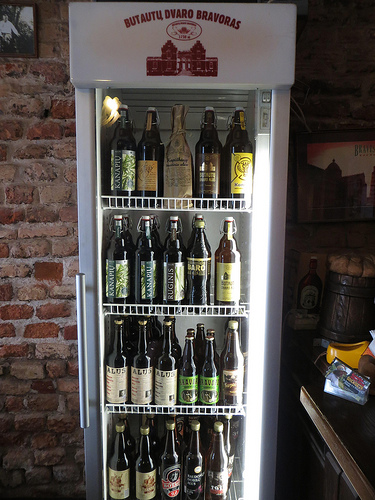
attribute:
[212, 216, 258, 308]
beer — fancy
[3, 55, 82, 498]
brick wall — red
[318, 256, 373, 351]
decoration —  wooden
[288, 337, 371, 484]
top — bar, wooden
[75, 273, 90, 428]
door handle — metal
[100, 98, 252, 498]
bottles — on top 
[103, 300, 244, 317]
shelf — second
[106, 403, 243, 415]
shelf — third 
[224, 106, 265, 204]
beer —   fancy 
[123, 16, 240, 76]
red lettering —  red 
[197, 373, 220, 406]
label — green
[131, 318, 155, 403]
beer bottle — fancy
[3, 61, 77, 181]
wall — brick 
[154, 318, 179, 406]
bottle — fancy, beer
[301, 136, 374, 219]
sign — advertisement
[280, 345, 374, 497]
counter top — wooden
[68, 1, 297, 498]
fridge — on top 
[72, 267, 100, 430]
handle — silver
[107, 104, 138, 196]
beer bottle —   fancy 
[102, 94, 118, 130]
light — reflection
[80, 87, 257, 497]
door — glass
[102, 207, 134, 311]
beer bottle —   fancy 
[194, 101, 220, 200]
bottle —   fancy 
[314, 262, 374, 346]
barrel — wooden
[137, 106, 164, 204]
bottle —   fancy 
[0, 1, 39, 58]
photo — small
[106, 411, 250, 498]
bottom shelf —  bottom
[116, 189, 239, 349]
beer bottle — fancy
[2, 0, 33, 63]
photograph — black, white, framed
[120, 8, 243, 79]
name — red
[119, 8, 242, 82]
advertisement — painted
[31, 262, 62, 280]
red brick —  red 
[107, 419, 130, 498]
beer — bottled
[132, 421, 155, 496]
beer — bottled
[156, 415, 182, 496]
beer — bottled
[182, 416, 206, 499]
beer — bottled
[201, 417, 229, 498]
beer — bottled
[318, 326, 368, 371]
decor — little yellow 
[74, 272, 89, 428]
handle — elongated, large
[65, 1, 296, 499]
cooler — beer, large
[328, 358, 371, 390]
cards — some business 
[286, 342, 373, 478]
counter top — top 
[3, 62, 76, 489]
wall — large, bricked